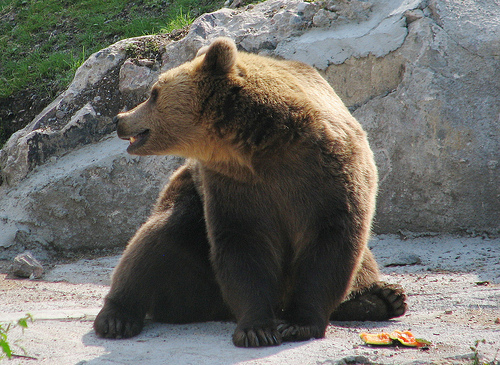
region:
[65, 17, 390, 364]
Large dark brown beat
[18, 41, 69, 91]
Small patch of green grass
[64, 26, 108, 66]
Small patch of green grass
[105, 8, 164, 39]
Small patch of green grass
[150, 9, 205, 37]
Small patch of green grass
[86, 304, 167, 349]
Dark brown bear claw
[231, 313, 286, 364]
Dark brown bear claw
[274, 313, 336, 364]
Dark brown bear claw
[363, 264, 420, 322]
Dark brown bear claw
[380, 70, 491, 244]
Part of a large grey rock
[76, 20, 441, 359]
a brown bear sitting on a man made rock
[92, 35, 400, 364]
brown bear sitting on cement block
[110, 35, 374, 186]
brown bear looking over its shoulder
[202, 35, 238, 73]
ear of a brown bear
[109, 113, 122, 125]
a bears black nose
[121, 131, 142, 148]
a bears yellow canine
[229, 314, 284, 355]
a bears paw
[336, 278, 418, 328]
a bears foot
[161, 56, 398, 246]
a bears brown fur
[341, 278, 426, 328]
a bears padded foot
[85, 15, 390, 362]
the bear is brown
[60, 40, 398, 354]
the bear is sitting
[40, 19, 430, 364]
a bear sitting down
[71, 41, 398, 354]
a brown bear sitting down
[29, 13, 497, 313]
a bear sitting outside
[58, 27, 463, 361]
a brown bear sitting outside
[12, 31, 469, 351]
a bear sitting on rocks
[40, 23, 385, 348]
a brown bear sitting on rocks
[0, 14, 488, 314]
a bear sitting in a rocky area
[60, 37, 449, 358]
a brown bear in a rocky area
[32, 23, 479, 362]
a brown in a large rocky area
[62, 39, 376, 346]
a brown bear in a large rocky area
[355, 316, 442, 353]
Food on the ground.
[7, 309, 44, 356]
Green leaves on the ground.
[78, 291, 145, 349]
Bear paws on the ground.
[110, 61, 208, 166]
Bear with open mouth.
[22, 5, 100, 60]
Patches of green grass.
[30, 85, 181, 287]
Big boulder block behind bear.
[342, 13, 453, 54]
Lighter shade of rocks behind bear.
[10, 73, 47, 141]
Small mound of dirt.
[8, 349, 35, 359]
Thin brown stick in ground.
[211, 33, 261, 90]
Top of bear's ear.